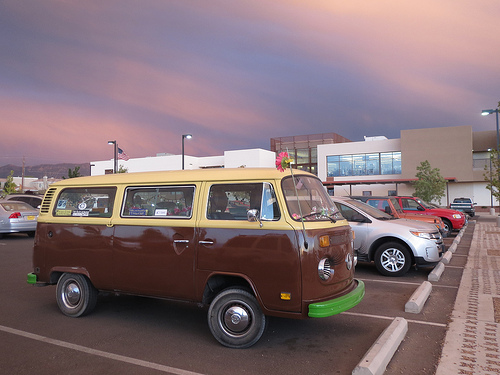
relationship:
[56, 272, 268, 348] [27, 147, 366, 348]
wheels on van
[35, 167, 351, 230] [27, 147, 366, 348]
light brown on van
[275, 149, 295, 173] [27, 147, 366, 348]
flower on van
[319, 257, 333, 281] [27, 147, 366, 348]
headlight on van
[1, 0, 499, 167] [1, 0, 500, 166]
clouds in sky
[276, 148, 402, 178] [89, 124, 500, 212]
lights in building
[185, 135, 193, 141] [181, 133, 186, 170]
light on pole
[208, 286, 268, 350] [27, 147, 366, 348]
wheel on van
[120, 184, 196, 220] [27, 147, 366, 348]
window on van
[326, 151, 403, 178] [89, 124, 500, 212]
window on building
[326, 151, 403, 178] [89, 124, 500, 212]
window in building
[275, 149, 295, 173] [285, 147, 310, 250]
flower on antenna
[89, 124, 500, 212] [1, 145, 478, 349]
building behind cars